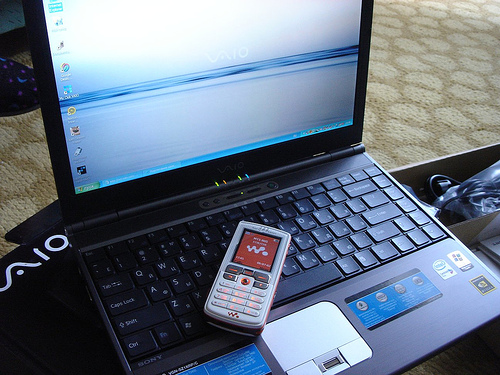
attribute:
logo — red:
[233, 227, 282, 272]